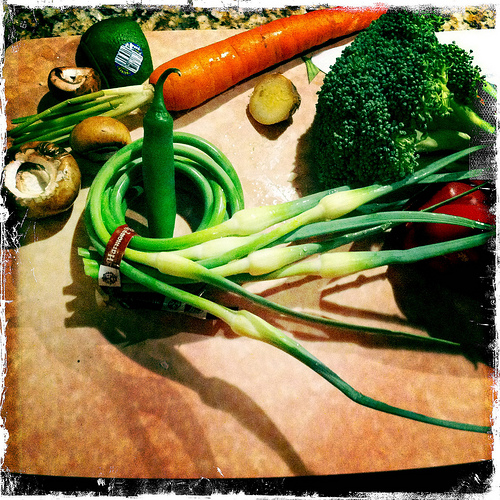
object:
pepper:
[140, 67, 180, 239]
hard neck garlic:
[77, 131, 495, 434]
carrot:
[8, 6, 392, 152]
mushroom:
[4, 139, 81, 219]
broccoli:
[292, 5, 497, 197]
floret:
[420, 86, 446, 107]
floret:
[434, 49, 448, 61]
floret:
[398, 139, 417, 174]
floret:
[333, 130, 355, 151]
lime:
[74, 16, 155, 90]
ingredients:
[8, 6, 493, 435]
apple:
[410, 183, 493, 250]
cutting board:
[7, 29, 494, 484]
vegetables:
[3, 8, 496, 435]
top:
[7, 73, 158, 160]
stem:
[10, 79, 156, 150]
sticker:
[113, 42, 144, 77]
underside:
[1, 155, 57, 200]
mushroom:
[68, 113, 133, 165]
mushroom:
[45, 63, 101, 101]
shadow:
[98, 327, 312, 475]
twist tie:
[95, 224, 142, 292]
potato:
[246, 73, 302, 128]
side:
[80, 151, 112, 161]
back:
[16, 203, 73, 221]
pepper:
[392, 168, 500, 272]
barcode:
[114, 40, 147, 76]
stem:
[150, 66, 183, 116]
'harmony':
[107, 226, 130, 264]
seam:
[78, 37, 112, 90]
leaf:
[298, 52, 322, 84]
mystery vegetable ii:
[399, 181, 497, 266]